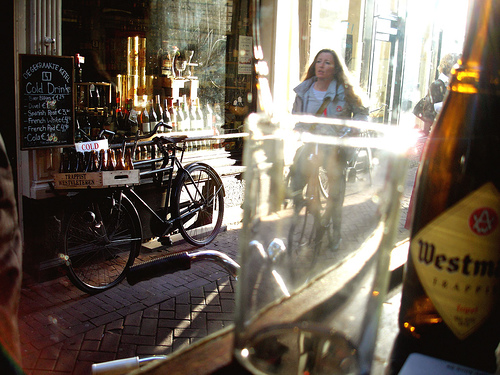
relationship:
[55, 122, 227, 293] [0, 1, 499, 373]
bike in bar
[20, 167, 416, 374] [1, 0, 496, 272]
sidewalk outside building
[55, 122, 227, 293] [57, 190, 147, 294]
bike has tire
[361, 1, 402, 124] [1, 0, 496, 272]
entrance into building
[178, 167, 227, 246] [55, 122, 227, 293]
wheel on bike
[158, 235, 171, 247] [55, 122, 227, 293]
pedal on bike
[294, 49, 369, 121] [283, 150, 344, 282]
woman on bike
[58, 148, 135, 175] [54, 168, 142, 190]
bottle on basket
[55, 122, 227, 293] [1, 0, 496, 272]
bike against building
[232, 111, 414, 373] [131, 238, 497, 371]
glass on table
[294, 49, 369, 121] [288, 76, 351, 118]
woman wearing jacket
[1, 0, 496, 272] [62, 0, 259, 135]
building has window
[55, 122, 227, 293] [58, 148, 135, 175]
bike has bottle